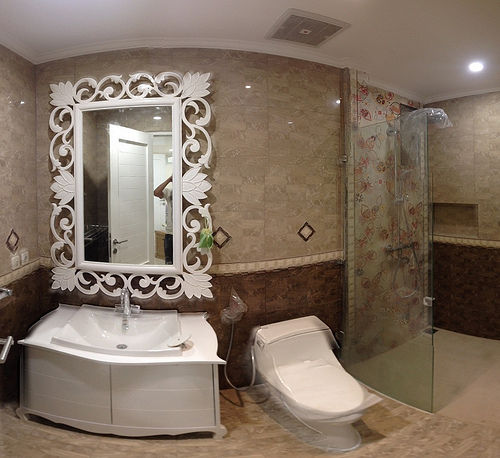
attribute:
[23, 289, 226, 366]
sink — clean, white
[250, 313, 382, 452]
toilet — modern, white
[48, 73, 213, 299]
mirror — white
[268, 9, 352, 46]
vent — bathroom , recessed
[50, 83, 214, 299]
frame — white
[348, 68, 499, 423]
shower — walk in, area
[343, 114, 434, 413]
partition — glass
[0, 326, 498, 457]
flooring — simulated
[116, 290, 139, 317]
faucet — chrome plated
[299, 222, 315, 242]
ornament — marble, diamond shaped, tile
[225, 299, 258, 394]
cable — water line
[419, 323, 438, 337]
object — white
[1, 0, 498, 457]
bathroom — private